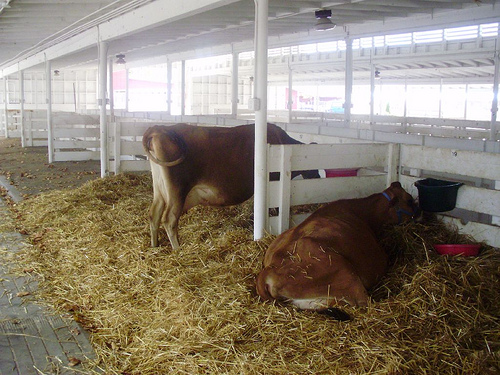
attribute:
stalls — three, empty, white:
[1, 37, 103, 167]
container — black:
[404, 174, 468, 214]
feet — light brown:
[129, 218, 214, 278]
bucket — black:
[414, 175, 463, 220]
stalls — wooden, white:
[0, 1, 496, 326]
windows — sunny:
[70, 73, 497, 128]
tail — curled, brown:
[141, 124, 188, 167]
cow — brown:
[270, 179, 435, 317]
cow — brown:
[141, 121, 321, 252]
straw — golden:
[12, 168, 498, 371]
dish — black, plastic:
[411, 172, 464, 214]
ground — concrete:
[1, 145, 495, 369]